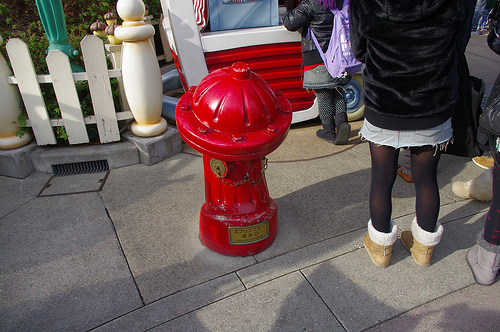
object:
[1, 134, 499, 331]
sidewalk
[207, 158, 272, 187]
chain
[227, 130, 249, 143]
bolt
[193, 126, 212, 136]
bolt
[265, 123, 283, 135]
bolt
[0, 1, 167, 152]
fence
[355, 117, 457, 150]
skirt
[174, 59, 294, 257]
fire hydrant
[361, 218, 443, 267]
boots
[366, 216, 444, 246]
fleece lining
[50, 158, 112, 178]
grate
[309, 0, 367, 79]
backpack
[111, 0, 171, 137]
fence pole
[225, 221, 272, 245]
plate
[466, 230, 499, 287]
boot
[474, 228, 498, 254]
fleece lining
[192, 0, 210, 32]
lines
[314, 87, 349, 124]
stockings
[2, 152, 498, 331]
shadows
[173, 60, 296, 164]
top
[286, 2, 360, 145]
girl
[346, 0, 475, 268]
woman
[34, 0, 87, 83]
pole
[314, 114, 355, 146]
uggs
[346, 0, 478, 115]
jacket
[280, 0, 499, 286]
people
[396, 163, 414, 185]
shoe